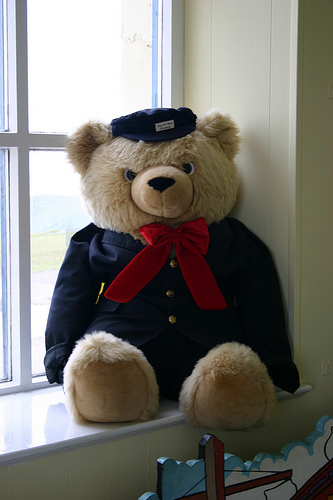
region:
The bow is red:
[111, 218, 226, 311]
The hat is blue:
[109, 104, 199, 144]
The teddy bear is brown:
[43, 109, 298, 427]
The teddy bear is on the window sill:
[43, 104, 302, 427]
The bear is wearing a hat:
[69, 110, 243, 234]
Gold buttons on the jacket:
[164, 258, 183, 330]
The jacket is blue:
[48, 216, 305, 395]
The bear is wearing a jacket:
[43, 218, 297, 401]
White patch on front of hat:
[152, 117, 176, 134]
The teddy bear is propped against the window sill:
[48, 110, 299, 427]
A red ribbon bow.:
[103, 218, 227, 312]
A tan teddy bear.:
[41, 110, 300, 427]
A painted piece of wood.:
[138, 415, 332, 499]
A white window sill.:
[0, 380, 188, 468]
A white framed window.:
[0, 0, 183, 393]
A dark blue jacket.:
[45, 216, 304, 392]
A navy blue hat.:
[110, 106, 198, 144]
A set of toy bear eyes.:
[122, 161, 193, 182]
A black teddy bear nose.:
[145, 174, 176, 195]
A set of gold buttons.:
[164, 258, 177, 324]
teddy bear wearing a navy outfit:
[34, 101, 310, 436]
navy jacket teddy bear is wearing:
[45, 229, 303, 385]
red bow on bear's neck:
[113, 225, 223, 313]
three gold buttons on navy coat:
[163, 252, 179, 326]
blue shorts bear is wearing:
[138, 326, 212, 387]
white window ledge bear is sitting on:
[1, 345, 310, 477]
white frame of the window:
[5, 1, 186, 389]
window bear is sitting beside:
[5, 3, 171, 386]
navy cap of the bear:
[108, 107, 196, 141]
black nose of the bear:
[144, 175, 172, 192]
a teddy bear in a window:
[42, 76, 271, 301]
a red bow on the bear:
[123, 209, 222, 326]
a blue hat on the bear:
[96, 90, 214, 153]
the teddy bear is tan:
[72, 135, 246, 219]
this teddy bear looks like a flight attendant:
[61, 103, 277, 334]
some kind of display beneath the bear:
[158, 421, 332, 493]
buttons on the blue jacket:
[158, 248, 189, 330]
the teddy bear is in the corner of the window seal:
[42, 89, 309, 348]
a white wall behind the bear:
[188, 5, 318, 194]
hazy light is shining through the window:
[31, 4, 158, 104]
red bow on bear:
[135, 218, 208, 263]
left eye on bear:
[176, 159, 199, 177]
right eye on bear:
[120, 160, 138, 187]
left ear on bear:
[199, 108, 240, 154]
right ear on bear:
[47, 121, 113, 164]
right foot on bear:
[63, 336, 160, 415]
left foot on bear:
[199, 349, 273, 421]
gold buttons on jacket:
[158, 259, 209, 342]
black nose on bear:
[149, 177, 172, 200]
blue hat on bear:
[118, 110, 214, 156]